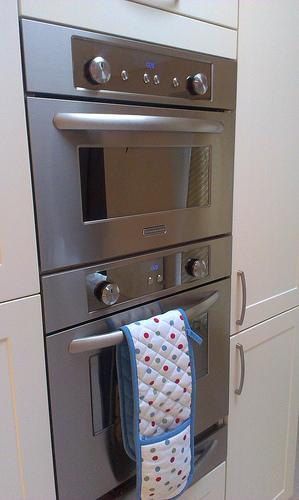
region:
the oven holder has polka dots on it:
[118, 303, 212, 495]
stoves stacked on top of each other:
[15, 11, 252, 492]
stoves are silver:
[14, 13, 248, 467]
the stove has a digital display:
[128, 50, 164, 72]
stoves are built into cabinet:
[0, 1, 296, 494]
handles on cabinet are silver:
[234, 261, 266, 407]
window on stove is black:
[76, 141, 226, 217]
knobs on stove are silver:
[68, 39, 226, 118]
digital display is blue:
[146, 58, 164, 75]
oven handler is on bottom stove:
[114, 309, 197, 497]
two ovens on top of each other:
[15, 19, 262, 485]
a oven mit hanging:
[112, 328, 227, 493]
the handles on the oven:
[24, 21, 241, 109]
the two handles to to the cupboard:
[224, 263, 252, 399]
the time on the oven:
[133, 46, 167, 70]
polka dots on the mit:
[139, 340, 186, 433]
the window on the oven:
[92, 165, 201, 197]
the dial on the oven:
[84, 59, 116, 91]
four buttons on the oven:
[117, 67, 184, 91]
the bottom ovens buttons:
[142, 271, 176, 284]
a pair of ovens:
[38, 11, 231, 497]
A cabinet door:
[236, 30, 297, 491]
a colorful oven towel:
[115, 309, 205, 499]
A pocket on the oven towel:
[140, 429, 198, 491]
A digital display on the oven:
[86, 242, 224, 313]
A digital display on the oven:
[63, 30, 215, 110]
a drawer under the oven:
[112, 423, 228, 497]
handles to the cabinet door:
[229, 271, 257, 405]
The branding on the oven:
[127, 219, 193, 237]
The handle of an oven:
[56, 106, 230, 144]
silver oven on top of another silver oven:
[10, 19, 256, 495]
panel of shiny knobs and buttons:
[72, 35, 216, 102]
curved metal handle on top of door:
[50, 102, 226, 141]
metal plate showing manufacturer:
[135, 219, 169, 235]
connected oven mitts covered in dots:
[108, 299, 232, 493]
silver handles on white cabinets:
[233, 168, 290, 488]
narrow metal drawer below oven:
[94, 413, 240, 493]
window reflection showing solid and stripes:
[69, 138, 212, 219]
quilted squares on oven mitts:
[119, 300, 190, 431]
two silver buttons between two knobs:
[81, 244, 221, 308]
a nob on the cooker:
[146, 275, 157, 286]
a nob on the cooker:
[157, 271, 169, 284]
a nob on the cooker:
[179, 254, 220, 280]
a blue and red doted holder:
[119, 305, 192, 498]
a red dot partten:
[146, 453, 160, 463]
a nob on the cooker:
[84, 53, 114, 83]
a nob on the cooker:
[142, 272, 154, 286]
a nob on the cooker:
[156, 275, 165, 286]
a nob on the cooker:
[182, 72, 213, 102]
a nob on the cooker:
[100, 282, 121, 309]